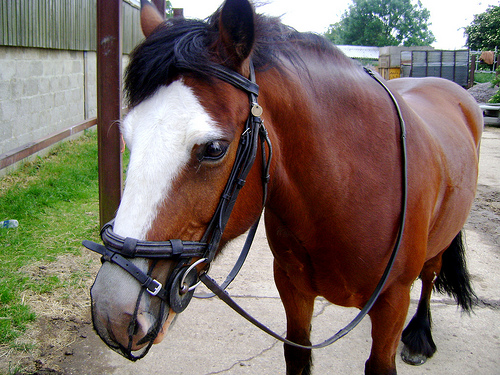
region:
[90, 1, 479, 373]
brown, white and black horse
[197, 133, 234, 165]
open brown horse eye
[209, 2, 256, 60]
brown colored horse ear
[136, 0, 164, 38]
brown colored horse ear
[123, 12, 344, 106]
black colored horse mane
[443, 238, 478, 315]
black colored horse hoof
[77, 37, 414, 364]
black leather horse bridle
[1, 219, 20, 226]
clear plastic water bottle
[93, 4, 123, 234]
tall rusted metal pole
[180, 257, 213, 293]
silver colored bridle ring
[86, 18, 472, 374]
A brown horse standing.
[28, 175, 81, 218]
Part of the grass.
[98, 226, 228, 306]
Part of the bridle.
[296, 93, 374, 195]
Sleek brown fur on shoulder.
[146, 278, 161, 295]
Silver buckle on the bridle.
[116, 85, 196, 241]
White stripe of horse's face.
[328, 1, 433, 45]
A green tree in the background.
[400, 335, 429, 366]
The left hoof on the horse.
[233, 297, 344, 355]
Part of the reins.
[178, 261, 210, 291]
part of the bit on the bridle.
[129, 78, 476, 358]
A horse standing in the staples.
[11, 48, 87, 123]
The wall is concrete.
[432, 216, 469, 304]
The end of the horse tail.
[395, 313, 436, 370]
Hair on the horse leg.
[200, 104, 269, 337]
The bridle is on the horse.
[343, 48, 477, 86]
Buildings behind the horse.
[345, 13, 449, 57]
Tree behind the building.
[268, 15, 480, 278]
The horse is brown.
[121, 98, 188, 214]
Face of horse is white.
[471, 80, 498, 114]
Pile of dirt on the side.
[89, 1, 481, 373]
a saddled horse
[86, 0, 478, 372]
a brown horse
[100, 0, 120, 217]
a red mettallic pole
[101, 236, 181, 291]
leather briddles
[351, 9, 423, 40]
a tall green tree on the background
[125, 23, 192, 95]
black mane on the head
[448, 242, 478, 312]
a blackish tail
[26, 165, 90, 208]
grass growing near the house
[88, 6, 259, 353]
the head is bron with black and white patches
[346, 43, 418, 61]
houses on the background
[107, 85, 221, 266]
a white patch on his head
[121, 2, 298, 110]
his mane is black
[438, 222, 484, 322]
his tail is black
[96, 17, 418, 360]
the horse is wearing a black harness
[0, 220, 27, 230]
a water bottle on the ground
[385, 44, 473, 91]
a truck behind the horse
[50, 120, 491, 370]
the horse is standing on a concrete patch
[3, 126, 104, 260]
a patch of green grass by the horse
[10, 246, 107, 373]
a patch of dead grass